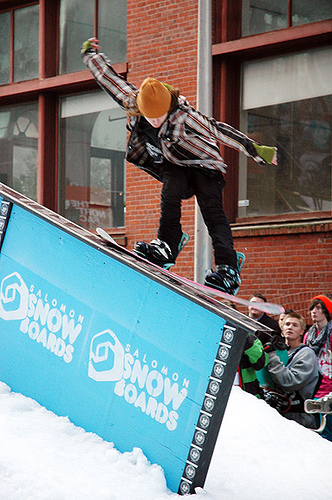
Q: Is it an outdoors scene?
A: Yes, it is outdoors.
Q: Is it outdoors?
A: Yes, it is outdoors.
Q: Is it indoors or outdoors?
A: It is outdoors.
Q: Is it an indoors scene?
A: No, it is outdoors.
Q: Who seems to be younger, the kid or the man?
A: The kid is younger than the man.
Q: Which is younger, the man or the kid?
A: The kid is younger than the man.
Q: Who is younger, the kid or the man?
A: The kid is younger than the man.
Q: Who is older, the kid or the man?
A: The man is older than the kid.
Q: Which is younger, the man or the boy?
A: The boy is younger than the man.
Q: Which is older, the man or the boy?
A: The man is older than the boy.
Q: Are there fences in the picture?
A: No, there are no fences.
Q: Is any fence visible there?
A: No, there are no fences.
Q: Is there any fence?
A: No, there are no fences.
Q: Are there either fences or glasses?
A: No, there are no fences or glasses.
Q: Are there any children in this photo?
A: Yes, there is a child.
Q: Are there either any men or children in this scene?
A: Yes, there is a child.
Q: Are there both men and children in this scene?
A: Yes, there are both a child and a man.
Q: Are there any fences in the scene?
A: No, there are no fences.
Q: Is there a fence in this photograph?
A: No, there are no fences.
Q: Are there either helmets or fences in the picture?
A: No, there are no fences or helmets.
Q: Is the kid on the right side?
A: Yes, the kid is on the right of the image.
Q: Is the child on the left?
A: No, the child is on the right of the image.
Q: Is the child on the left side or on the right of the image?
A: The child is on the right of the image.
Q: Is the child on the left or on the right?
A: The child is on the right of the image.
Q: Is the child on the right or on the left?
A: The child is on the right of the image.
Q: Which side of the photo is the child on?
A: The child is on the right of the image.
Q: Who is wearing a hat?
A: The kid is wearing a hat.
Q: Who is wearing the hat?
A: The kid is wearing a hat.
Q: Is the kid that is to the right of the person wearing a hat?
A: Yes, the kid is wearing a hat.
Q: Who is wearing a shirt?
A: The kid is wearing a shirt.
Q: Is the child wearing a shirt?
A: Yes, the child is wearing a shirt.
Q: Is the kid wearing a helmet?
A: No, the kid is wearing a shirt.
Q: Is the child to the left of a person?
A: No, the child is to the right of a person.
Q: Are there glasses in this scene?
A: No, there are no glasses.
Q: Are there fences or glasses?
A: No, there are no glasses or fences.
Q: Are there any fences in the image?
A: No, there are no fences.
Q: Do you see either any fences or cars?
A: No, there are no fences or cars.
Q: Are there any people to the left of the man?
A: Yes, there is a person to the left of the man.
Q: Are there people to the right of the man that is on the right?
A: No, the person is to the left of the man.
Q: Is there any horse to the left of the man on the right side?
A: No, there is a person to the left of the man.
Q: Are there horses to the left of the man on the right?
A: No, there is a person to the left of the man.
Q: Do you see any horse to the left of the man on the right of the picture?
A: No, there is a person to the left of the man.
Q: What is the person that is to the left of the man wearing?
A: The person is wearing a shirt.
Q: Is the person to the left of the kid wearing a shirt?
A: Yes, the person is wearing a shirt.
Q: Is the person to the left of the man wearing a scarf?
A: No, the person is wearing a shirt.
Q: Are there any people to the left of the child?
A: Yes, there is a person to the left of the child.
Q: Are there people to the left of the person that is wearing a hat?
A: Yes, there is a person to the left of the child.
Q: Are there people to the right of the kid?
A: No, the person is to the left of the kid.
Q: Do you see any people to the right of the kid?
A: No, the person is to the left of the kid.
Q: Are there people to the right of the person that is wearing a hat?
A: No, the person is to the left of the kid.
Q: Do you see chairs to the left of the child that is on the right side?
A: No, there is a person to the left of the kid.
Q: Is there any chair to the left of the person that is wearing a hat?
A: No, there is a person to the left of the kid.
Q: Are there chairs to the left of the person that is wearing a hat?
A: No, there is a person to the left of the kid.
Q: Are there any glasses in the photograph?
A: No, there are no glasses.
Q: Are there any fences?
A: No, there are no fences.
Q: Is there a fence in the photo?
A: No, there are no fences.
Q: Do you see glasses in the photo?
A: No, there are no glasses.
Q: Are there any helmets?
A: No, there are no helmets.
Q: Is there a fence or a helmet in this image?
A: No, there are no helmets or fences.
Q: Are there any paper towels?
A: No, there are no paper towels.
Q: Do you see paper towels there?
A: No, there are no paper towels.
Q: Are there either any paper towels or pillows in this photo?
A: No, there are no paper towels or pillows.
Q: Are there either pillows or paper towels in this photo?
A: No, there are no paper towels or pillows.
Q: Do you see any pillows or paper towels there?
A: No, there are no paper towels or pillows.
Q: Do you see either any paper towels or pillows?
A: No, there are no paper towels or pillows.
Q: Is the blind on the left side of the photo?
A: Yes, the blind is on the left of the image.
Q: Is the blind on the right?
A: No, the blind is on the left of the image.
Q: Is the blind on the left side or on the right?
A: The blind is on the left of the image.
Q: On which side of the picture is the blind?
A: The blind is on the left of the image.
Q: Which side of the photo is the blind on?
A: The blind is on the left of the image.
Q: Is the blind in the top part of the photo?
A: Yes, the blind is in the top of the image.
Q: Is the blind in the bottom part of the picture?
A: No, the blind is in the top of the image.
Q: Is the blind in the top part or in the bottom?
A: The blind is in the top of the image.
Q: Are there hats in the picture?
A: Yes, there is a hat.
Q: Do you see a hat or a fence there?
A: Yes, there is a hat.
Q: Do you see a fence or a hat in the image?
A: Yes, there is a hat.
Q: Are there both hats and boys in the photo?
A: Yes, there are both a hat and a boy.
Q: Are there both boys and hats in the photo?
A: Yes, there are both a hat and a boy.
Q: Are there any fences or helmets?
A: No, there are no helmets or fences.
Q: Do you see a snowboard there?
A: Yes, there is a snowboard.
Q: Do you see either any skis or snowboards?
A: Yes, there is a snowboard.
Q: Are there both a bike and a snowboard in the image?
A: No, there is a snowboard but no bikes.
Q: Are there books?
A: No, there are no books.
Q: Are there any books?
A: No, there are no books.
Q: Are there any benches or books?
A: No, there are no books or benches.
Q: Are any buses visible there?
A: No, there are no buses.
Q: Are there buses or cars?
A: No, there are no buses or cars.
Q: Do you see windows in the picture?
A: Yes, there is a window.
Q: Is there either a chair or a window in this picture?
A: Yes, there is a window.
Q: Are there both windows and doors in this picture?
A: No, there is a window but no doors.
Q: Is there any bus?
A: No, there are no buses.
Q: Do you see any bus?
A: No, there are no buses.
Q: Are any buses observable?
A: No, there are no buses.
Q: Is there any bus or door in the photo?
A: No, there are no buses or doors.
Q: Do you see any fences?
A: No, there are no fences.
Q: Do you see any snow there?
A: Yes, there is snow.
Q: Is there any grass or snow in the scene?
A: Yes, there is snow.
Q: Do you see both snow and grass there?
A: No, there is snow but no grass.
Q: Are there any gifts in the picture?
A: No, there are no gifts.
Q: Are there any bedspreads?
A: No, there are no bedspreads.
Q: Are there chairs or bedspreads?
A: No, there are no bedspreads or chairs.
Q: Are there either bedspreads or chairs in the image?
A: No, there are no bedspreads or chairs.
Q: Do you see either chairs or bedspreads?
A: No, there are no bedspreads or chairs.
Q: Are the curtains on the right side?
A: Yes, the curtains are on the right of the image.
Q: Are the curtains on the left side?
A: No, the curtains are on the right of the image.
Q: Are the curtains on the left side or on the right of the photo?
A: The curtains are on the right of the image.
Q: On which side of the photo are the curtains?
A: The curtains are on the right of the image.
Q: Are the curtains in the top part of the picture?
A: Yes, the curtains are in the top of the image.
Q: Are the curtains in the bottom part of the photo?
A: No, the curtains are in the top of the image.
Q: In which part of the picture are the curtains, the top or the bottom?
A: The curtains are in the top of the image.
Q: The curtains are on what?
A: The curtains are on the window.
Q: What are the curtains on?
A: The curtains are on the window.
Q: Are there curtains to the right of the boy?
A: Yes, there are curtains to the right of the boy.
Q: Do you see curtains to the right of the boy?
A: Yes, there are curtains to the right of the boy.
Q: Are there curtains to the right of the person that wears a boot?
A: Yes, there are curtains to the right of the boy.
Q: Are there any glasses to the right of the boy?
A: No, there are curtains to the right of the boy.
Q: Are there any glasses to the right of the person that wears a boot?
A: No, there are curtains to the right of the boy.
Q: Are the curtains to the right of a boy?
A: Yes, the curtains are to the right of a boy.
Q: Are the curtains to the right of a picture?
A: No, the curtains are to the right of a boy.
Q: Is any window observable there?
A: Yes, there is a window.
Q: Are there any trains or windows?
A: Yes, there is a window.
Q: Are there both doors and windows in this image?
A: No, there is a window but no doors.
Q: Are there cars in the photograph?
A: No, there are no cars.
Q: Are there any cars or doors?
A: No, there are no cars or doors.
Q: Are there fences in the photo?
A: No, there are no fences.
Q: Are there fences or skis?
A: No, there are no fences or skis.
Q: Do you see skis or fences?
A: No, there are no fences or skis.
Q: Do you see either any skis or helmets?
A: No, there are no helmets or skis.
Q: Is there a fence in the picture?
A: No, there are no fences.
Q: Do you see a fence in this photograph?
A: No, there are no fences.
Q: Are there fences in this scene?
A: No, there are no fences.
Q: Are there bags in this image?
A: No, there are no bags.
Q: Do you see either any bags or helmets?
A: No, there are no bags or helmets.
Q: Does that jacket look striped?
A: Yes, the jacket is striped.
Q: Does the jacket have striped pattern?
A: Yes, the jacket is striped.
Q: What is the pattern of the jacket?
A: The jacket is striped.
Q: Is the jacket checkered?
A: No, the jacket is striped.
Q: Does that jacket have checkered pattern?
A: No, the jacket is striped.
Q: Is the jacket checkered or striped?
A: The jacket is striped.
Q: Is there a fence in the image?
A: No, there are no fences.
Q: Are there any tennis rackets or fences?
A: No, there are no fences or tennis rackets.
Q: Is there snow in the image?
A: Yes, there is snow.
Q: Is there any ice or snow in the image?
A: Yes, there is snow.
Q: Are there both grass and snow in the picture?
A: No, there is snow but no grass.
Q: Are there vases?
A: No, there are no vases.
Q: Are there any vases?
A: No, there are no vases.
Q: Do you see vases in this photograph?
A: No, there are no vases.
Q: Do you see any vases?
A: No, there are no vases.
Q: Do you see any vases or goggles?
A: No, there are no vases or goggles.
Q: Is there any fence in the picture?
A: No, there are no fences.